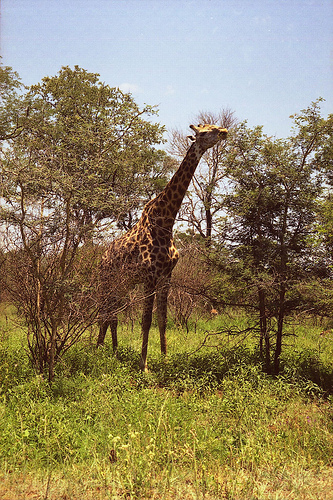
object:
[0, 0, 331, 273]
sky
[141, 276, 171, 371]
legs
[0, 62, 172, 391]
tree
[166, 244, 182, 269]
bump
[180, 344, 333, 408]
shadow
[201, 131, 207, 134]
eye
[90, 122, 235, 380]
giraffe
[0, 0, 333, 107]
clouds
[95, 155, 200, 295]
spots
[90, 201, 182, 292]
body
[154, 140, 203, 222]
neck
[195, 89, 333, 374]
tree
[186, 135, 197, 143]
ear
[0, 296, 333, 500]
field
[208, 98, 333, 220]
leaves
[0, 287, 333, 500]
grass